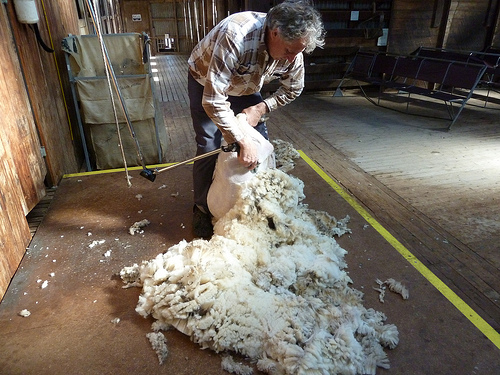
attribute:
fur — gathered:
[210, 247, 257, 268]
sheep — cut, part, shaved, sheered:
[208, 195, 229, 214]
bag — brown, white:
[127, 141, 128, 142]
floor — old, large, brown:
[370, 127, 380, 131]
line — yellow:
[353, 188, 374, 210]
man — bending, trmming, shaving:
[211, 3, 309, 153]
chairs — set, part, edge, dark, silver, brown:
[427, 46, 435, 52]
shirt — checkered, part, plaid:
[215, 34, 240, 44]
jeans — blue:
[196, 178, 207, 184]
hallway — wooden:
[192, 7, 211, 17]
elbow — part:
[204, 96, 207, 113]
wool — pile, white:
[192, 309, 244, 349]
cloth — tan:
[137, 44, 148, 51]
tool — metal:
[258, 152, 273, 172]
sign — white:
[346, 8, 361, 24]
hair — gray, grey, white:
[293, 17, 309, 38]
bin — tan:
[124, 89, 141, 105]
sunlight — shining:
[424, 152, 451, 166]